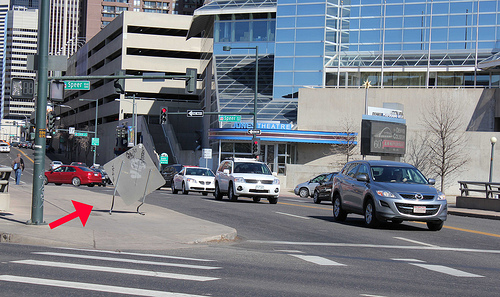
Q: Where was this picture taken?
A: Downtown in a city.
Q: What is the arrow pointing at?
A: A road sign.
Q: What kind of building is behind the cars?
A: A theatre.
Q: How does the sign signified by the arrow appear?
A: Bent.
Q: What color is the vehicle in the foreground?
A: Gray.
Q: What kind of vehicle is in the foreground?
A: SUV.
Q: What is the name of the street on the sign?
A: Speer St.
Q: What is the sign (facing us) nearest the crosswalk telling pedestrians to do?
A: Walk.